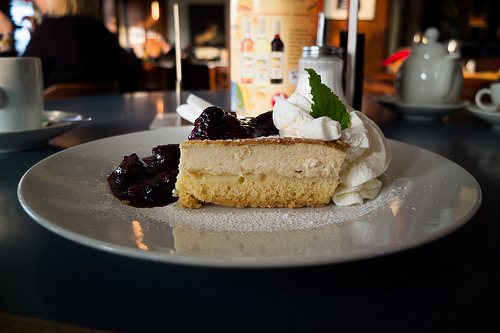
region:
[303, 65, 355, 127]
The mint leaf on the whipped cream of the dessert.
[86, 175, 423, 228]
The sprinkles of powder sugar on the white dish.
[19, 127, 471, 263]
The white dish the dessert is placed on.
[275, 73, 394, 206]
The whipped cream on the dessert.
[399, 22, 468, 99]
The white tea kettle on the right.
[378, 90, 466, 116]
The white dish the tea kettle is placed on.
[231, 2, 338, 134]
The menu behind the plate with the dessert.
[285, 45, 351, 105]
The sugar jar behind the dessert plate.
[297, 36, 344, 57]
The silver cap on the sugar jar.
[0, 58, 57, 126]
The coffee mug on the left that is placed on a white dish.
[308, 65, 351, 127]
mint leaf on a dessert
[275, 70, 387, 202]
whipped cream with a mint leaf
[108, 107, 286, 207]
fruit topping for a cake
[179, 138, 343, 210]
a piece of white cake with cream filling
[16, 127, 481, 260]
a white china plate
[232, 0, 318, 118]
advertisment with wine bottles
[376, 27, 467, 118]
white china tea pot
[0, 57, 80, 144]
coffee mug on the left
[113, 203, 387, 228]
dusting of powdered sugar on the plate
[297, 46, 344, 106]
sugar dispenser behind the dessert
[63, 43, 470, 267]
a white plate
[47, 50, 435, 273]
a white plate with food on it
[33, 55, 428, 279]
a white plate with a dessert on it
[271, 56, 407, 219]
white whipped cream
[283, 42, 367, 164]
a green mint leaf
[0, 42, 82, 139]
a white coffee mug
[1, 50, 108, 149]
a white coffee mug on a white saucer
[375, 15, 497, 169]
a white teapot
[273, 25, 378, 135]
a sugar container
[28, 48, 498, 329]
a black table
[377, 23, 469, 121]
white porcelain tea kettle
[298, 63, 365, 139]
green leaf in the cool whip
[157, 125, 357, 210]
a layered piece of pie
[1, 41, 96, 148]
a white mug on a white saucer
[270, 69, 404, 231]
cool whip on part of the pie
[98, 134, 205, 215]
dark colored jam on the plate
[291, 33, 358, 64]
silver lid to glass jar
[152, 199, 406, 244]
white sprinkles along the plate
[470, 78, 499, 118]
handle of a tea cup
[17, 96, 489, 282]
a piece of pie on a white plate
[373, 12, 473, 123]
The teapot is white.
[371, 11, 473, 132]
The teapot is breakable.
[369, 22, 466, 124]
The teapot is on a plate.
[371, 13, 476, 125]
The teapot has a lid.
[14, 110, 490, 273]
The plate is white.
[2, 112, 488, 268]
The plate is round.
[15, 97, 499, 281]
The plate is circular.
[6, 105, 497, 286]
The plate is disclike.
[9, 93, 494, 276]
The plate is in use.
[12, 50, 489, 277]
Dessert is on the plate.